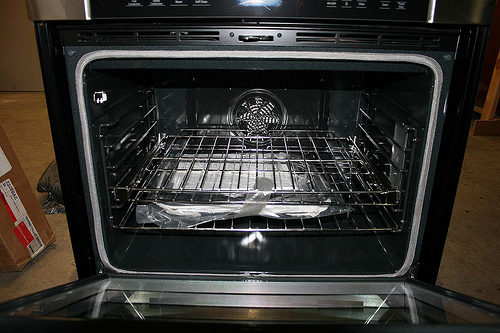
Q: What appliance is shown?
A: Oven.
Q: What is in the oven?
A: Tinfoil.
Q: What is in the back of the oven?
A: Fan.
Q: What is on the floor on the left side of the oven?
A: Box.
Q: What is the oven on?
A: Floor.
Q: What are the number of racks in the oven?
A: 3.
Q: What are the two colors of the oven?
A: Black and silver.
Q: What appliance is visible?
A: Oven.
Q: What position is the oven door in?
A: Open.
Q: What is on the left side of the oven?
A: Box.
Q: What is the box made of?
A: Cardboard.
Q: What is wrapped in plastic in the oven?
A: Paper.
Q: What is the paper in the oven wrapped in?
A: Plastic.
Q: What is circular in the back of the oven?
A: Vent.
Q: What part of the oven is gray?
A: The inside.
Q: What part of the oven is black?
A: The outside.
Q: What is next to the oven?
A: A cardboard box.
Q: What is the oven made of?
A: Metal.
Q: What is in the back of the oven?
A: An exhaust fan.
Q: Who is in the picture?
A: No one.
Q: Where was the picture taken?
A: In a oven.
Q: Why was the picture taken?
A: To capture the inside of the oven.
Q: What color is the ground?
A: Tan.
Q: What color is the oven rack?
A: Gray.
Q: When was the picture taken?
A: Prior to installing the oven.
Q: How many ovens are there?
A: 1.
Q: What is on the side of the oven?
A: A box.